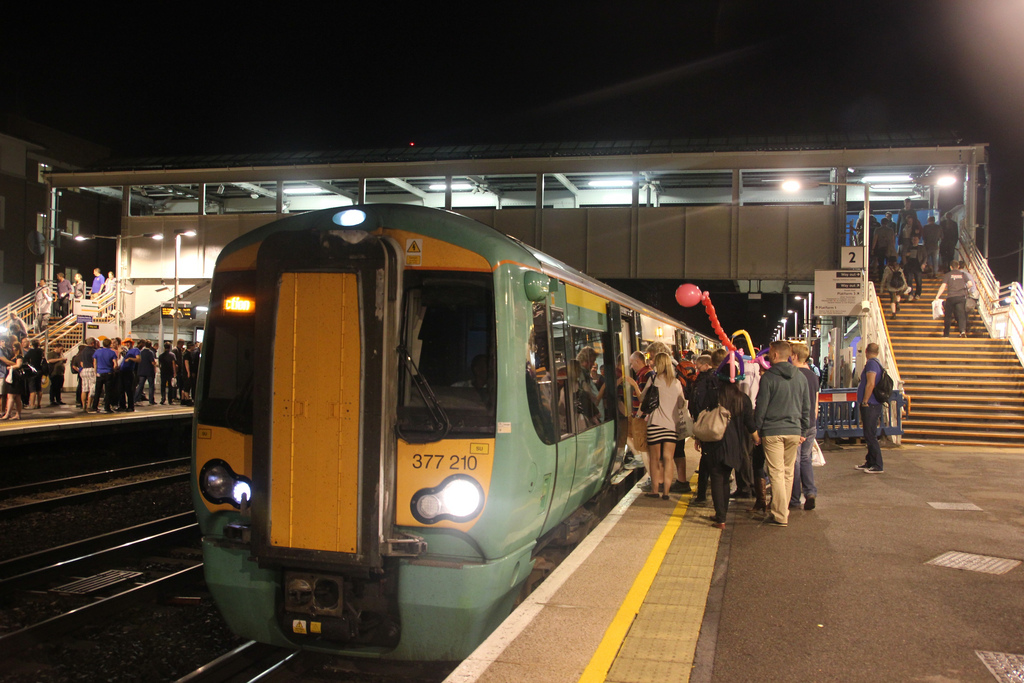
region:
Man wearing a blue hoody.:
[744, 337, 814, 534]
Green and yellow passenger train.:
[178, 193, 723, 668]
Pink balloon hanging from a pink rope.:
[669, 278, 745, 352]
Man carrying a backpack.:
[848, 337, 899, 477]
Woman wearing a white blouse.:
[637, 345, 682, 504]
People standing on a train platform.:
[4, 329, 198, 425]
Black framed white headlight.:
[406, 473, 483, 527]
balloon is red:
[674, 277, 701, 304]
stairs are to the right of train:
[867, 264, 1020, 443]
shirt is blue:
[93, 349, 113, 369]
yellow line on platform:
[576, 473, 693, 677]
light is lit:
[409, 469, 483, 523]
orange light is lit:
[217, 292, 255, 313]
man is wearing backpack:
[855, 339, 894, 476]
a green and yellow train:
[202, 190, 753, 665]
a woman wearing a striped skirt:
[634, 348, 693, 500]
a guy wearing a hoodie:
[754, 338, 824, 528]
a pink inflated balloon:
[672, 282, 708, 314]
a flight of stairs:
[857, 239, 1022, 449]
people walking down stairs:
[2, 269, 116, 365]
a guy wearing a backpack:
[847, 342, 904, 476]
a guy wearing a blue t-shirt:
[852, 337, 906, 478]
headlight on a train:
[411, 465, 485, 530]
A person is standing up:
[751, 339, 806, 521]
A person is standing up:
[638, 354, 684, 494]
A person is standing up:
[94, 333, 114, 410]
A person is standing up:
[116, 340, 132, 405]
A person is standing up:
[136, 340, 155, 385]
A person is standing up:
[158, 333, 177, 400]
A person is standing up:
[183, 337, 200, 395]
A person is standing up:
[935, 264, 973, 331]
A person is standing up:
[904, 239, 931, 294]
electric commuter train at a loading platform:
[183, 187, 733, 678]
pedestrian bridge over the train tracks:
[46, 145, 993, 319]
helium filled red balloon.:
[669, 284, 737, 357]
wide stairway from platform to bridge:
[849, 259, 1023, 443]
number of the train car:
[400, 446, 487, 485]